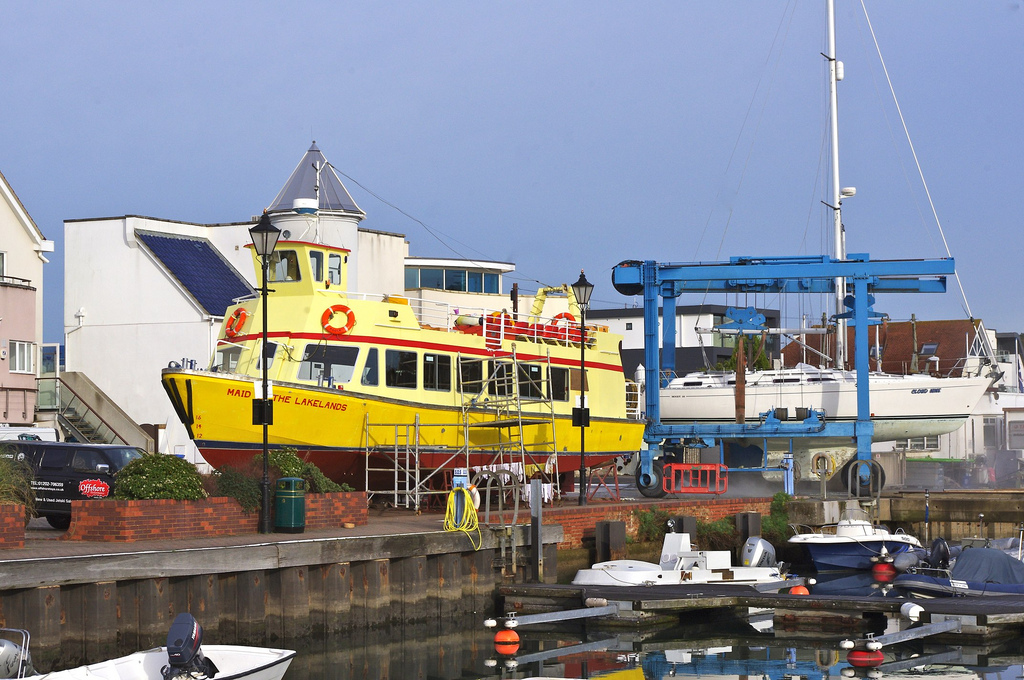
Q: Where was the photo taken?
A: Harbor.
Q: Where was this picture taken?
A: Near the boats.